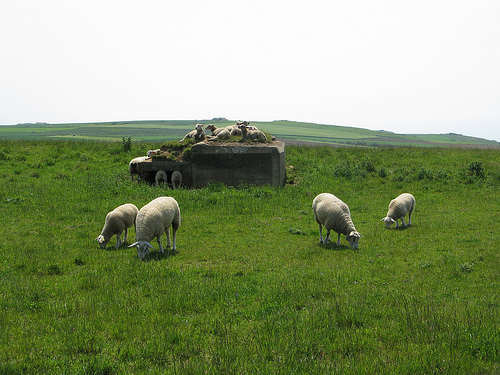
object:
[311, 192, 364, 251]
sheep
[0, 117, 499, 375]
field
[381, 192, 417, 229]
sheep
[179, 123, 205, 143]
sheep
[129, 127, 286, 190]
structure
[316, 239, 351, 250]
shadow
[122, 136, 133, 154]
plant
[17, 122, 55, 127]
trees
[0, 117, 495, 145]
hill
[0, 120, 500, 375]
grass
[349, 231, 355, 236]
ears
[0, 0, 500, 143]
sky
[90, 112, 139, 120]
distance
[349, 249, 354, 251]
down